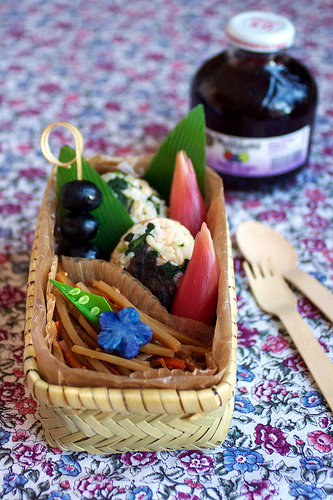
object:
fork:
[241, 258, 333, 424]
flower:
[97, 306, 152, 360]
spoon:
[237, 219, 333, 323]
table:
[0, 0, 331, 498]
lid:
[225, 10, 295, 53]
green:
[145, 103, 207, 201]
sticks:
[58, 340, 92, 369]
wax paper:
[31, 149, 231, 382]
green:
[130, 241, 138, 248]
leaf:
[143, 105, 208, 195]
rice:
[162, 230, 188, 243]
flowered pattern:
[13, 19, 57, 115]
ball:
[101, 168, 170, 219]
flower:
[129, 200, 158, 220]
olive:
[60, 179, 104, 212]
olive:
[54, 212, 100, 243]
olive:
[54, 241, 97, 260]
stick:
[39, 119, 84, 178]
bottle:
[186, 10, 317, 191]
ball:
[109, 216, 200, 312]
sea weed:
[109, 216, 200, 309]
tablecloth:
[1, 2, 331, 496]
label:
[204, 125, 311, 176]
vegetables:
[168, 151, 225, 311]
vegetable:
[49, 278, 156, 359]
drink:
[192, 51, 316, 190]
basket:
[22, 143, 240, 457]